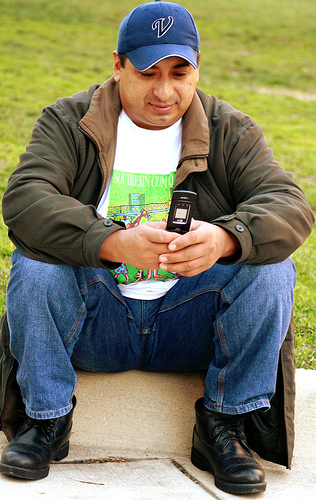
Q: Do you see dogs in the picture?
A: No, there are no dogs.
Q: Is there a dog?
A: No, there are no dogs.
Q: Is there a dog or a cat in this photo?
A: No, there are no dogs or cats.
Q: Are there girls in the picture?
A: No, there are no girls.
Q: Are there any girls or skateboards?
A: No, there are no girls or skateboards.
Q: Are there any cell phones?
A: Yes, there is a cell phone.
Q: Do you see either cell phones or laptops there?
A: Yes, there is a cell phone.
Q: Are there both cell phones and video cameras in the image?
A: No, there is a cell phone but no video cameras.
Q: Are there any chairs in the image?
A: No, there are no chairs.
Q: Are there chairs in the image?
A: No, there are no chairs.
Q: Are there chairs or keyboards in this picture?
A: No, there are no chairs or keyboards.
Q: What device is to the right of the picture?
A: The device is a cell phone.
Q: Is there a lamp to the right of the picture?
A: No, there is a cell phone to the right of the picture.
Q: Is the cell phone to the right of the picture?
A: Yes, the cell phone is to the right of the picture.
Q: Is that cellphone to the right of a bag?
A: No, the cellphone is to the right of the picture.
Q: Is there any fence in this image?
A: No, there are no fences.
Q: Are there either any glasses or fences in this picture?
A: No, there are no fences or glasses.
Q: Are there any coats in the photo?
A: Yes, there is a coat.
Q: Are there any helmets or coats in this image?
A: Yes, there is a coat.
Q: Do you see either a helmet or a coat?
A: Yes, there is a coat.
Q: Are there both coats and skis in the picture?
A: No, there is a coat but no skis.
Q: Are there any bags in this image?
A: No, there are no bags.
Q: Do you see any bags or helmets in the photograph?
A: No, there are no bags or helmets.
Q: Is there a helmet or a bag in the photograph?
A: No, there are no bags or helmets.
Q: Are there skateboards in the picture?
A: No, there are no skateboards.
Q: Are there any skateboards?
A: No, there are no skateboards.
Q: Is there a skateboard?
A: No, there are no skateboards.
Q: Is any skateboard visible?
A: No, there are no skateboards.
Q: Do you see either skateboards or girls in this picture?
A: No, there are no skateboards or girls.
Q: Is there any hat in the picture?
A: Yes, there is a hat.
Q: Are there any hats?
A: Yes, there is a hat.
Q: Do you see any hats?
A: Yes, there is a hat.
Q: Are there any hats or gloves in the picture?
A: Yes, there is a hat.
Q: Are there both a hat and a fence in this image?
A: No, there is a hat but no fences.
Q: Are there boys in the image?
A: No, there are no boys.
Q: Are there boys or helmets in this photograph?
A: No, there are no boys or helmets.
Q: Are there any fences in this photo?
A: No, there are no fences.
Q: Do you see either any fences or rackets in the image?
A: No, there are no fences or rackets.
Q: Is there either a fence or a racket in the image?
A: No, there are no fences or rackets.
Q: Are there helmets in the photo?
A: No, there are no helmets.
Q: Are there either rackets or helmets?
A: No, there are no helmets or rackets.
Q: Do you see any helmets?
A: No, there are no helmets.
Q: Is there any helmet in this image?
A: No, there are no helmets.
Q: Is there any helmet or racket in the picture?
A: No, there are no helmets or rackets.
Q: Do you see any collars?
A: Yes, there is a collar.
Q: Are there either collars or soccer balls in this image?
A: Yes, there is a collar.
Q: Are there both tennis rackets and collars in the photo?
A: No, there is a collar but no rackets.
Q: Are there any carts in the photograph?
A: No, there are no carts.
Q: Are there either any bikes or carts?
A: No, there are no carts or bikes.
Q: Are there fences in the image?
A: No, there are no fences.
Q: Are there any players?
A: No, there are no players.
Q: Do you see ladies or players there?
A: No, there are no players or ladies.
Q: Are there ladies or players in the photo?
A: No, there are no players or ladies.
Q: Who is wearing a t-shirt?
A: The man is wearing a t-shirt.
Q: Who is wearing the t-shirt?
A: The man is wearing a t-shirt.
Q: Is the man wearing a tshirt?
A: Yes, the man is wearing a tshirt.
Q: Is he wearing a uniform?
A: No, the man is wearing a tshirt.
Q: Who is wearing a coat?
A: The man is wearing a coat.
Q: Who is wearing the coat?
A: The man is wearing a coat.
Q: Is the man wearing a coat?
A: Yes, the man is wearing a coat.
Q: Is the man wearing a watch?
A: No, the man is wearing a coat.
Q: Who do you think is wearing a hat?
A: The man is wearing a hat.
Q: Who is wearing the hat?
A: The man is wearing a hat.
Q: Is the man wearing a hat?
A: Yes, the man is wearing a hat.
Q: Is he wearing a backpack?
A: No, the man is wearing a hat.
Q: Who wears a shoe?
A: The man wears a shoe.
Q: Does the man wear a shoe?
A: Yes, the man wears a shoe.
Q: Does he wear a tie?
A: No, the man wears a shoe.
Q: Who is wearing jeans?
A: The man is wearing jeans.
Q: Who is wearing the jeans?
A: The man is wearing jeans.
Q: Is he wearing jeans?
A: Yes, the man is wearing jeans.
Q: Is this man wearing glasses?
A: No, the man is wearing jeans.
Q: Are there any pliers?
A: No, there are no pliers.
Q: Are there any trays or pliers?
A: No, there are no pliers or trays.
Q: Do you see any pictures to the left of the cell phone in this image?
A: Yes, there is a picture to the left of the cell phone.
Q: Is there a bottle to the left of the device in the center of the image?
A: No, there is a picture to the left of the cell phone.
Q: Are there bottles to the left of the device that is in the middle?
A: No, there is a picture to the left of the cell phone.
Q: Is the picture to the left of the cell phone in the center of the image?
A: Yes, the picture is to the left of the mobile phone.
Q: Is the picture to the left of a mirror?
A: No, the picture is to the left of the mobile phone.